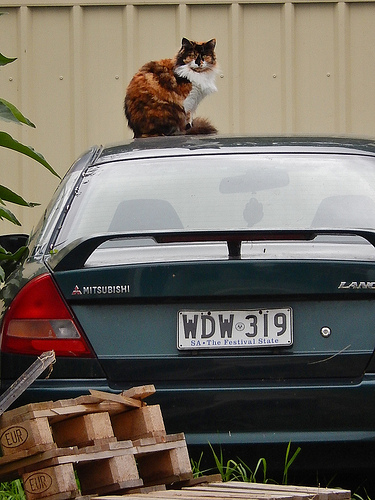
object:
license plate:
[178, 294, 296, 354]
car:
[0, 136, 375, 477]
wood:
[4, 350, 194, 500]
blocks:
[0, 406, 147, 496]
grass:
[0, 204, 35, 287]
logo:
[65, 281, 136, 302]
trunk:
[47, 227, 375, 403]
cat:
[124, 38, 224, 137]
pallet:
[98, 438, 207, 485]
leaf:
[2, 98, 37, 129]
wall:
[239, 17, 353, 120]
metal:
[227, 19, 311, 40]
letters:
[184, 313, 240, 340]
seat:
[111, 193, 187, 241]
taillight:
[3, 275, 91, 357]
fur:
[155, 78, 189, 103]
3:
[246, 313, 260, 338]